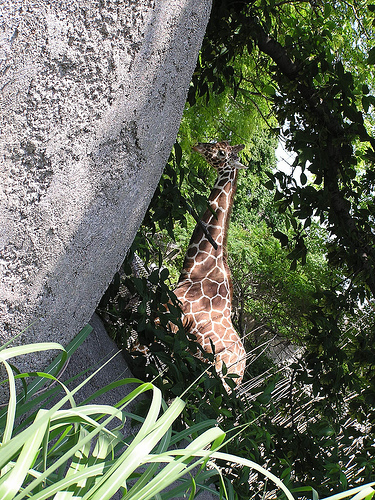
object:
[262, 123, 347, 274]
leaves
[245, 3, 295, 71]
branch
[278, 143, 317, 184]
sky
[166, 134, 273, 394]
giraffe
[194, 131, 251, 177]
head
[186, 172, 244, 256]
neck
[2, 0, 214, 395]
cement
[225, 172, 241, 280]
mane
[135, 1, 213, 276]
shadow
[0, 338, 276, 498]
grass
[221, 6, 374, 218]
tree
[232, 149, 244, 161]
horn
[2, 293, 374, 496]
weeds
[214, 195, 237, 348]
light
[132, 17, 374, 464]
wild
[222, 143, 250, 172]
ears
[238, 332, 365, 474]
plant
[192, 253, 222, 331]
spots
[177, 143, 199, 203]
food